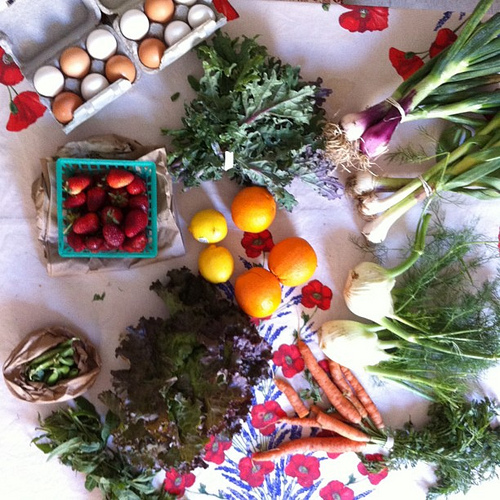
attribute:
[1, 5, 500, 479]
cloth — white, floral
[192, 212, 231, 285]
lemons — yellow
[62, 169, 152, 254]
strawberries — pinted, white, red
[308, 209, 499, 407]
fennel — pieces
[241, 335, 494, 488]
carrots — broken, bunched, topped, orange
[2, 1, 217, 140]
eggs — opened, brown, cartoned, white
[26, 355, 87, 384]
beans — green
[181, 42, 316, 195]
vegetables — green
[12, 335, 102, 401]
bag — brown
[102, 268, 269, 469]
lettuce — purple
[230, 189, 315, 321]
oranges — orange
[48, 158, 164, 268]
box — green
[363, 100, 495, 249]
onions — green, types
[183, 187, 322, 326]
fruit — citrus, similar, yellow, bright, orange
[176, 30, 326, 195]
greens — small, leafy